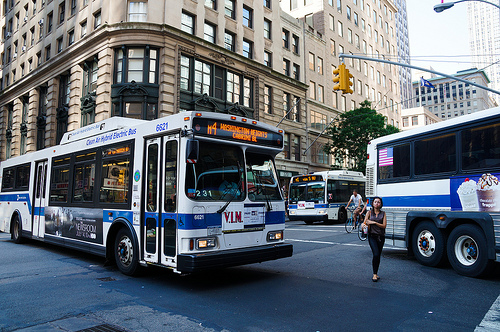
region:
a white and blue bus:
[0, 105, 296, 281]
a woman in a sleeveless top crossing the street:
[357, 194, 394, 284]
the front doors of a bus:
[137, 132, 195, 282]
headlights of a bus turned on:
[180, 231, 293, 250]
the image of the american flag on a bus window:
[371, 143, 397, 169]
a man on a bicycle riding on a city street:
[343, 187, 365, 232]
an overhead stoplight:
[325, 58, 362, 94]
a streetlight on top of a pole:
[425, 0, 495, 15]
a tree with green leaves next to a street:
[330, 100, 390, 166]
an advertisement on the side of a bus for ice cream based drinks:
[453, 172, 496, 210]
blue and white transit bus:
[32, 119, 274, 252]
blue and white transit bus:
[180, 119, 287, 251]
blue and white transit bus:
[371, 136, 498, 188]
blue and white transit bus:
[281, 174, 331, 214]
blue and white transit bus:
[320, 175, 338, 225]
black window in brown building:
[195, 16, 221, 48]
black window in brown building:
[177, 55, 212, 95]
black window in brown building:
[108, 40, 170, 87]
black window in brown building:
[301, 49, 326, 74]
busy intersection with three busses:
[10, 77, 485, 326]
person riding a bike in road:
[340, 192, 366, 237]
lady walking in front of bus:
[360, 192, 390, 283]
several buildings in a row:
[10, 7, 495, 115]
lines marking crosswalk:
[284, 220, 372, 255]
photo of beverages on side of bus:
[447, 169, 499, 212]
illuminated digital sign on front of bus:
[184, 112, 285, 152]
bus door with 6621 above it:
[140, 113, 182, 273]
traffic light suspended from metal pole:
[317, 46, 495, 97]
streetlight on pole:
[426, 2, 498, 19]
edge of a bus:
[155, 171, 195, 258]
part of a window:
[203, 142, 250, 202]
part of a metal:
[385, 37, 420, 91]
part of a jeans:
[359, 229, 379, 262]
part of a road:
[304, 265, 340, 303]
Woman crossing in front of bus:
[360, 193, 388, 283]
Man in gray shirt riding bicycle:
[339, 183, 366, 239]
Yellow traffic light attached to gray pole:
[328, 63, 358, 95]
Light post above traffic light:
[432, 0, 499, 35]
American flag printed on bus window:
[378, 141, 395, 171]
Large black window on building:
[110, 42, 160, 91]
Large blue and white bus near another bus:
[0, 108, 314, 278]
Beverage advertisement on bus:
[447, 174, 499, 214]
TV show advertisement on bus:
[37, 201, 103, 246]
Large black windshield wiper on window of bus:
[214, 169, 244, 219]